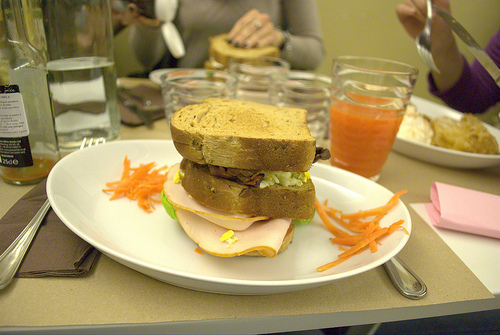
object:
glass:
[330, 54, 420, 181]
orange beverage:
[327, 96, 407, 177]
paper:
[424, 181, 499, 239]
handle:
[383, 255, 429, 300]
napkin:
[0, 176, 99, 279]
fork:
[0, 198, 51, 291]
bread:
[160, 96, 331, 259]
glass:
[44, 0, 121, 157]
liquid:
[45, 55, 118, 152]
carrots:
[313, 189, 411, 271]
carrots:
[101, 154, 170, 214]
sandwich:
[159, 97, 331, 259]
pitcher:
[114, 0, 325, 77]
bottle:
[0, 0, 61, 187]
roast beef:
[193, 162, 265, 187]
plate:
[45, 138, 412, 296]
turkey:
[193, 164, 266, 188]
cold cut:
[159, 97, 330, 258]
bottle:
[41, 0, 120, 159]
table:
[0, 180, 500, 335]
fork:
[415, 0, 442, 75]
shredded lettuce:
[259, 170, 310, 190]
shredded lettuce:
[161, 190, 178, 220]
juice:
[328, 84, 411, 180]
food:
[420, 112, 500, 155]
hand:
[393, 0, 484, 113]